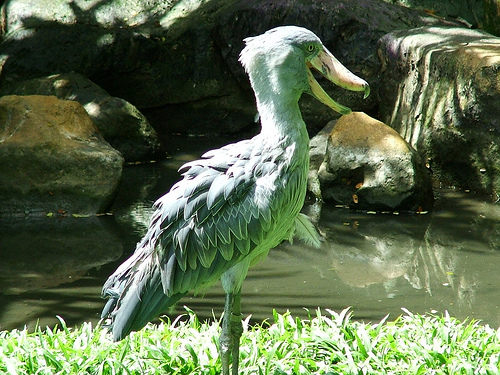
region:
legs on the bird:
[203, 227, 268, 365]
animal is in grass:
[196, 10, 308, 365]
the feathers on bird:
[155, 95, 340, 341]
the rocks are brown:
[5, 6, 182, 181]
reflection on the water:
[303, 220, 473, 306]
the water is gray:
[31, 207, 216, 320]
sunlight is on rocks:
[10, 5, 205, 76]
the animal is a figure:
[196, 15, 358, 372]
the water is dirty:
[26, 215, 314, 322]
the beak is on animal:
[248, 15, 369, 128]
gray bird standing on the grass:
[82, 7, 390, 374]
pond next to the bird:
[11, 204, 497, 320]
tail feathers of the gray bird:
[103, 256, 163, 336]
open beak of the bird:
[313, 51, 368, 121]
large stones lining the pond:
[12, 7, 498, 192]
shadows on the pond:
[12, 208, 494, 314]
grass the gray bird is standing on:
[6, 304, 498, 374]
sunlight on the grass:
[2, 304, 492, 374]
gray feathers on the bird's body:
[137, 153, 282, 277]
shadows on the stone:
[11, 1, 268, 101]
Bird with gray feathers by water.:
[85, 19, 373, 373]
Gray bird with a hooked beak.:
[91, 21, 376, 372]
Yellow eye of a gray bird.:
[95, 15, 375, 372]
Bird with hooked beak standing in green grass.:
[92, 21, 390, 373]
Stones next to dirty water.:
[2, 62, 164, 336]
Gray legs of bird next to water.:
[94, 13, 372, 370]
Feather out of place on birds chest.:
[225, 12, 376, 269]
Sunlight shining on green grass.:
[295, 255, 497, 370]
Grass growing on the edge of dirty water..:
[298, 256, 493, 371]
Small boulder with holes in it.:
[304, 105, 432, 210]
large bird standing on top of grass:
[97, 25, 372, 373]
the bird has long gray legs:
[221, 290, 243, 374]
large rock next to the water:
[0, 76, 125, 215]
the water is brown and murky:
[0, 212, 498, 331]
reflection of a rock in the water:
[324, 214, 416, 287]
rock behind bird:
[300, 106, 417, 216]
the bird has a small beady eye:
[307, 42, 312, 48]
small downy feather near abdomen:
[295, 212, 323, 248]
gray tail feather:
[108, 263, 155, 342]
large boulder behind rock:
[357, 23, 498, 218]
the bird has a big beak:
[222, 8, 382, 130]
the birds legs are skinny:
[200, 233, 286, 373]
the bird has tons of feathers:
[100, 110, 302, 257]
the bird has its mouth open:
[225, 8, 383, 123]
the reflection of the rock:
[297, 216, 463, 286]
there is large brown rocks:
[3, 63, 166, 202]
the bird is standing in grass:
[160, 303, 474, 370]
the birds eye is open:
[278, 23, 334, 60]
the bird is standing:
[82, 10, 381, 364]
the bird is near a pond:
[58, 6, 473, 373]